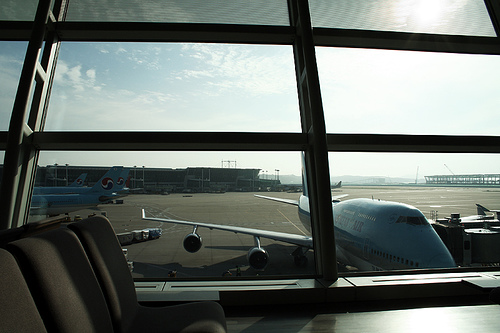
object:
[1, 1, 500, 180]
sky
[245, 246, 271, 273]
engines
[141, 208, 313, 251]
wing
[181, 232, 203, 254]
engines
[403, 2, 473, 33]
sun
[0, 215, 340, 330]
shadow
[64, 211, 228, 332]
chairs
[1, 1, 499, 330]
airport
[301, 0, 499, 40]
window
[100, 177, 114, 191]
circle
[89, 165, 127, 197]
tail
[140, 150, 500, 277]
plane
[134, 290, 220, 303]
table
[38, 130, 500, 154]
ledge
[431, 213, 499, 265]
overhang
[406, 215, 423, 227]
windshield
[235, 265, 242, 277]
man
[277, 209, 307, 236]
line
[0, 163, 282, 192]
building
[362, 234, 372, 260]
door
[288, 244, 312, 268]
stabilizer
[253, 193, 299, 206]
fins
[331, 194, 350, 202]
fins